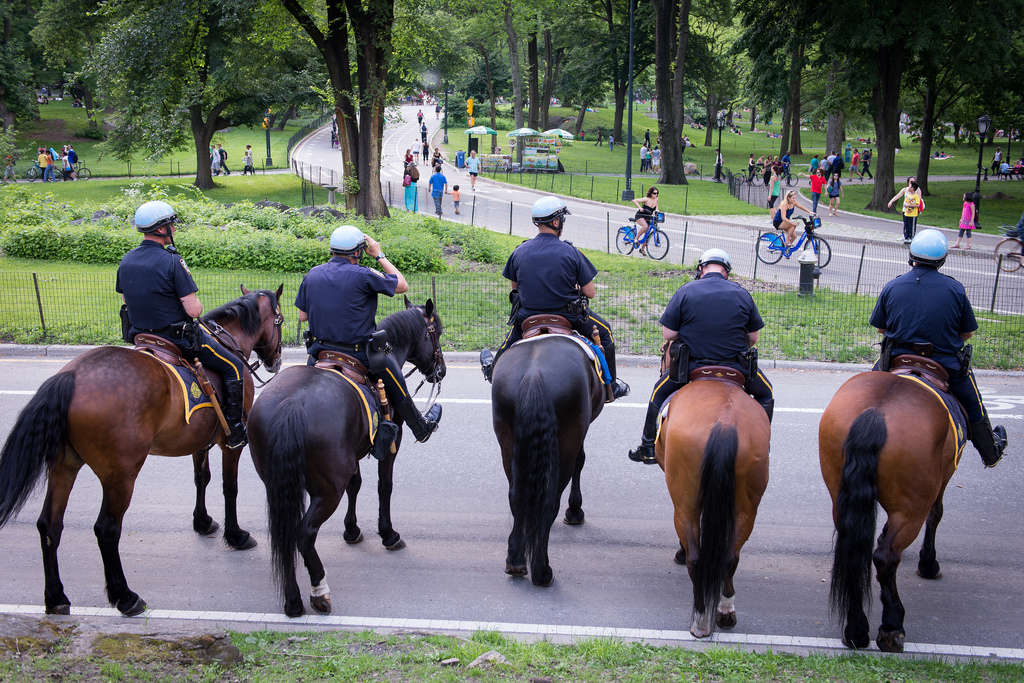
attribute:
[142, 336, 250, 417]
cloth — black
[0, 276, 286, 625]
horse — gold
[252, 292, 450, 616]
horse — brown, black